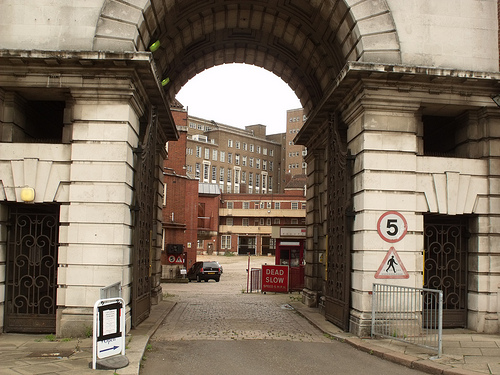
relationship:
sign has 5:
[376, 208, 410, 244] [385, 215, 401, 239]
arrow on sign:
[96, 343, 121, 354] [91, 296, 126, 369]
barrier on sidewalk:
[365, 279, 450, 361] [1, 327, 143, 374]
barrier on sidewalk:
[365, 279, 450, 361] [361, 322, 497, 372]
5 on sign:
[386, 217, 399, 236] [379, 210, 407, 243]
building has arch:
[2, 1, 499, 373] [121, 3, 364, 337]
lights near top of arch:
[127, 30, 182, 113] [136, 3, 357, 349]